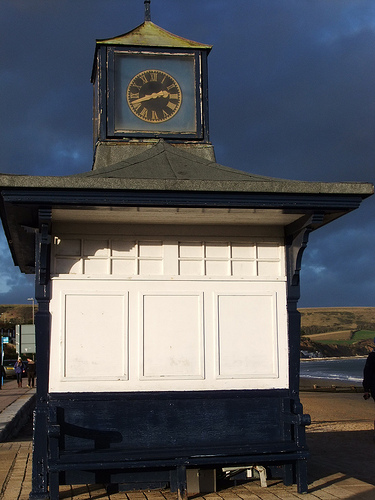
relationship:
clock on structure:
[108, 56, 196, 133] [2, 3, 375, 499]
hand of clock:
[132, 96, 153, 106] [108, 56, 196, 133]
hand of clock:
[154, 91, 170, 96] [108, 56, 196, 133]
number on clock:
[150, 70, 158, 86] [108, 56, 196, 133]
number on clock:
[143, 74, 150, 84] [108, 56, 196, 133]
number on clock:
[131, 83, 144, 91] [108, 56, 196, 133]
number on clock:
[130, 92, 140, 100] [108, 56, 196, 133]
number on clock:
[140, 106, 149, 120] [108, 56, 196, 133]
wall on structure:
[48, 233, 289, 395] [2, 3, 375, 499]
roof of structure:
[0, 140, 374, 276] [2, 3, 375, 499]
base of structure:
[24, 452, 324, 499] [2, 3, 375, 499]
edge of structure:
[22, 206, 46, 500] [2, 3, 375, 499]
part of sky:
[1, 221, 41, 311] [2, 0, 374, 304]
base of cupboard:
[24, 452, 324, 499] [2, 3, 375, 499]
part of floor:
[1, 439, 32, 500] [3, 421, 373, 499]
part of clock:
[127, 70, 181, 123] [108, 56, 196, 133]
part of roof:
[0, 176, 373, 193] [0, 140, 374, 276]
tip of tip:
[142, 2, 154, 4] [142, 0, 155, 22]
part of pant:
[31, 375, 36, 389] [27, 370, 37, 388]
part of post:
[297, 463, 307, 493] [285, 234, 307, 494]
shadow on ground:
[305, 431, 373, 499] [0, 305, 372, 498]